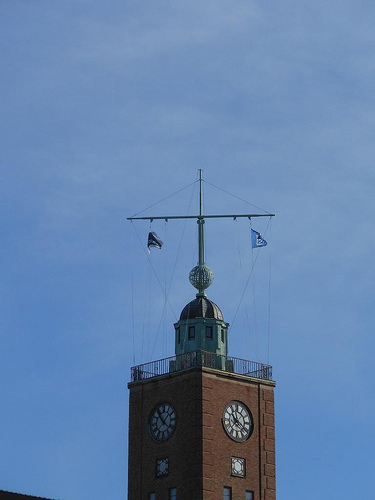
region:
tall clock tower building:
[97, 162, 302, 498]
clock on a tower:
[221, 397, 259, 447]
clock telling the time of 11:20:
[140, 393, 188, 448]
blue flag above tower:
[249, 227, 267, 252]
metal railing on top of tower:
[121, 351, 274, 383]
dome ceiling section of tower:
[171, 293, 233, 377]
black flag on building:
[138, 227, 170, 252]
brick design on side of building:
[259, 387, 278, 498]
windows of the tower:
[216, 481, 259, 498]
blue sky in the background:
[21, 34, 359, 157]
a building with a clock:
[48, 139, 283, 466]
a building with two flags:
[105, 161, 325, 457]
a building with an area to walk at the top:
[80, 325, 314, 405]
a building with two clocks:
[121, 376, 291, 447]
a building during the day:
[98, 147, 317, 450]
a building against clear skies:
[69, 183, 292, 423]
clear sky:
[22, 116, 167, 187]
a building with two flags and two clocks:
[97, 178, 339, 437]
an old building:
[89, 188, 321, 455]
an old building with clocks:
[101, 373, 356, 478]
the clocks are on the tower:
[114, 354, 281, 497]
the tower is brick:
[124, 357, 275, 498]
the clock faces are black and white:
[145, 392, 260, 444]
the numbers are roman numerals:
[143, 397, 259, 448]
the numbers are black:
[148, 400, 252, 446]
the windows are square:
[143, 452, 250, 479]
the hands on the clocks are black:
[156, 400, 246, 435]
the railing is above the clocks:
[125, 349, 279, 393]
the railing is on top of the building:
[128, 347, 276, 388]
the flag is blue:
[244, 226, 275, 251]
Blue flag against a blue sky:
[244, 227, 270, 247]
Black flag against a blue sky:
[142, 229, 165, 252]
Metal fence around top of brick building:
[199, 347, 276, 383]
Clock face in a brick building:
[218, 394, 257, 447]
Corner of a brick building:
[189, 373, 214, 492]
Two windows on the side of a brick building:
[220, 482, 252, 499]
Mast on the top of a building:
[103, 169, 283, 298]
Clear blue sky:
[287, 288, 358, 411]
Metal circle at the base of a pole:
[183, 260, 214, 291]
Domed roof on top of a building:
[166, 295, 231, 323]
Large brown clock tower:
[96, 190, 329, 496]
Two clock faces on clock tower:
[110, 387, 314, 457]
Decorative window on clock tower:
[214, 447, 291, 495]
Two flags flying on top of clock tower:
[105, 190, 309, 299]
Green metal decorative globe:
[164, 240, 281, 334]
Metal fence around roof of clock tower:
[200, 329, 303, 458]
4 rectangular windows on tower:
[162, 322, 249, 364]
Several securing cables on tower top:
[105, 190, 207, 369]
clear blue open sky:
[253, 332, 372, 495]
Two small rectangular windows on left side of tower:
[116, 477, 199, 498]